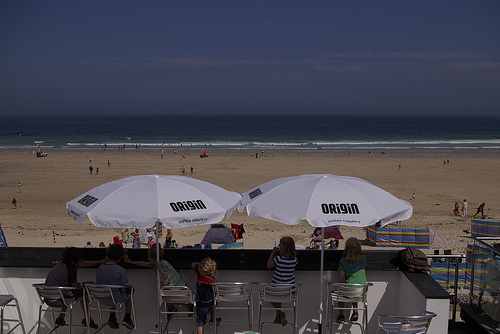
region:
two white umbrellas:
[38, 145, 428, 332]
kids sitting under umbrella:
[35, 240, 397, 330]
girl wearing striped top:
[250, 222, 327, 300]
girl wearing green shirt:
[330, 224, 398, 317]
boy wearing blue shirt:
[88, 227, 142, 314]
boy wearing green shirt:
[140, 246, 204, 301]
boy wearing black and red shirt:
[190, 257, 223, 321]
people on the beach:
[11, 138, 498, 206]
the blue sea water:
[17, 111, 499, 158]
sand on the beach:
[3, 130, 494, 288]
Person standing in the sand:
[5, 172, 40, 202]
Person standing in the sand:
[3, 190, 29, 220]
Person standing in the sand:
[26, 139, 48, 164]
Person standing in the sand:
[82, 161, 104, 173]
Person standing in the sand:
[153, 142, 212, 165]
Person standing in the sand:
[438, 196, 475, 225]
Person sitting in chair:
[325, 237, 372, 314]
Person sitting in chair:
[256, 227, 297, 323]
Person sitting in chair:
[189, 252, 229, 332]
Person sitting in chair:
[140, 241, 192, 329]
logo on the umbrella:
[314, 200, 361, 213]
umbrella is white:
[250, 168, 421, 228]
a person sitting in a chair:
[269, 237, 298, 290]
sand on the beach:
[233, 160, 292, 174]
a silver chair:
[82, 286, 122, 307]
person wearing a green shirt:
[342, 253, 369, 283]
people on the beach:
[84, 165, 104, 175]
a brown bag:
[400, 246, 430, 270]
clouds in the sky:
[166, 56, 371, 80]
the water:
[215, 115, 318, 140]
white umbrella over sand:
[77, 162, 217, 234]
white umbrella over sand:
[232, 170, 403, 239]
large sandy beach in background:
[25, 152, 495, 254]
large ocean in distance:
[25, 107, 494, 137]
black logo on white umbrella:
[317, 196, 375, 224]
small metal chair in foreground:
[36, 279, 73, 319]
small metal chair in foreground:
[91, 279, 130, 332]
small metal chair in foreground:
[166, 282, 198, 329]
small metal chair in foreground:
[213, 284, 264, 327]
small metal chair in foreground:
[259, 281, 312, 331]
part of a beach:
[426, 155, 443, 165]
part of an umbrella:
[329, 184, 341, 194]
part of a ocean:
[310, 118, 319, 128]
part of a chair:
[230, 282, 240, 299]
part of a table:
[239, 257, 243, 262]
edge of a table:
[222, 231, 242, 266]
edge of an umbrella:
[296, 194, 311, 220]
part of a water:
[411, 225, 414, 231]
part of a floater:
[417, 136, 426, 193]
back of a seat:
[234, 286, 241, 297]